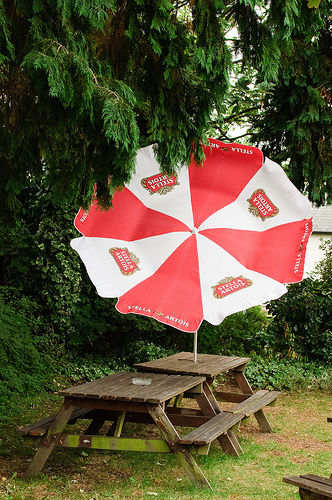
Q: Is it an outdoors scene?
A: Yes, it is outdoors.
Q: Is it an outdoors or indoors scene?
A: It is outdoors.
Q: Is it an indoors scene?
A: No, it is outdoors.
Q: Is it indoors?
A: No, it is outdoors.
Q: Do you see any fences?
A: No, there are no fences.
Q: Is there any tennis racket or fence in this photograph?
A: No, there are no fences or rackets.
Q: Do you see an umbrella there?
A: Yes, there is an umbrella.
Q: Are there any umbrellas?
A: Yes, there is an umbrella.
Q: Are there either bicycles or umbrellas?
A: Yes, there is an umbrella.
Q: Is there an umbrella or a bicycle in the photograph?
A: Yes, there is an umbrella.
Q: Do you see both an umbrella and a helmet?
A: No, there is an umbrella but no helmets.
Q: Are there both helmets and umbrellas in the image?
A: No, there is an umbrella but no helmets.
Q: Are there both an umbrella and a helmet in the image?
A: No, there is an umbrella but no helmets.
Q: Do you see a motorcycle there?
A: No, there are no motorcycles.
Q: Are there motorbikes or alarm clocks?
A: No, there are no motorbikes or alarm clocks.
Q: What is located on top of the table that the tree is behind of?
A: The umbrella is on top of the table.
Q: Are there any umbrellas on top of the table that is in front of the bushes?
A: Yes, there is an umbrella on top of the table.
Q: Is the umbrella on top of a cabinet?
A: No, the umbrella is on top of a table.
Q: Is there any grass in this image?
A: Yes, there is grass.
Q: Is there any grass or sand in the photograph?
A: Yes, there is grass.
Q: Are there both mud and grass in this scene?
A: No, there is grass but no mud.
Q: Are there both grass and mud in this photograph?
A: No, there is grass but no mud.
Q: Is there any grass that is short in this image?
A: Yes, there is short grass.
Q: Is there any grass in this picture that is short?
A: Yes, there is grass that is short.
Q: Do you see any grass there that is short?
A: Yes, there is grass that is short.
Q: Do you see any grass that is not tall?
A: Yes, there is short grass.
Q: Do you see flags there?
A: No, there are no flags.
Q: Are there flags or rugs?
A: No, there are no flags or rugs.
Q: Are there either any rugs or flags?
A: No, there are no flags or rugs.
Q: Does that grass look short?
A: Yes, the grass is short.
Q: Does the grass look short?
A: Yes, the grass is short.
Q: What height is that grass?
A: The grass is short.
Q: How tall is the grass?
A: The grass is short.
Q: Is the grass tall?
A: No, the grass is short.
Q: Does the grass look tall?
A: No, the grass is short.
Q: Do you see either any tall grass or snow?
A: No, there is grass but it is short.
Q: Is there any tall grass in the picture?
A: No, there is grass but it is short.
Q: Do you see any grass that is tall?
A: No, there is grass but it is short.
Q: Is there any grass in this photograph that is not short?
A: No, there is grass but it is short.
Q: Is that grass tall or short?
A: The grass is short.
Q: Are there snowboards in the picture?
A: No, there are no snowboards.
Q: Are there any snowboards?
A: No, there are no snowboards.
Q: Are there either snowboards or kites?
A: No, there are no snowboards or kites.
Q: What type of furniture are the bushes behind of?
A: The bushes are behind the table.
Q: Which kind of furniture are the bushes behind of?
A: The bushes are behind the table.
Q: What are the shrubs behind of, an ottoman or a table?
A: The shrubs are behind a table.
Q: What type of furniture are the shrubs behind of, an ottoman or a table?
A: The shrubs are behind a table.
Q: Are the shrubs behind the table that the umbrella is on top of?
A: Yes, the shrubs are behind the table.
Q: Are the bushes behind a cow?
A: No, the bushes are behind the table.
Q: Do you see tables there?
A: Yes, there is a table.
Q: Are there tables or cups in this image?
A: Yes, there is a table.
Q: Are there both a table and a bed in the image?
A: No, there is a table but no beds.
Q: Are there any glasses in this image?
A: No, there are no glasses.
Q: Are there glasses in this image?
A: No, there are no glasses.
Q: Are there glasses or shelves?
A: No, there are no glasses or shelves.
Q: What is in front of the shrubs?
A: The table is in front of the shrubs.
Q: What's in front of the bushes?
A: The table is in front of the shrubs.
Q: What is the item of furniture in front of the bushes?
A: The piece of furniture is a table.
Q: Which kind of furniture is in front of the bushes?
A: The piece of furniture is a table.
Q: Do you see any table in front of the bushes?
A: Yes, there is a table in front of the bushes.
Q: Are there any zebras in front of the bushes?
A: No, there is a table in front of the bushes.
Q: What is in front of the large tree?
A: The table is in front of the tree.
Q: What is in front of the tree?
A: The table is in front of the tree.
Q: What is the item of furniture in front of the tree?
A: The piece of furniture is a table.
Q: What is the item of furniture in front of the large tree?
A: The piece of furniture is a table.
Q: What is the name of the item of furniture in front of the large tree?
A: The piece of furniture is a table.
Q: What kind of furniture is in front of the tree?
A: The piece of furniture is a table.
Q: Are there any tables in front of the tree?
A: Yes, there is a table in front of the tree.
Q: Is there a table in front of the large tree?
A: Yes, there is a table in front of the tree.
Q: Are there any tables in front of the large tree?
A: Yes, there is a table in front of the tree.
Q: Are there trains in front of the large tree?
A: No, there is a table in front of the tree.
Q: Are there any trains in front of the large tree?
A: No, there is a table in front of the tree.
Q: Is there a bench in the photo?
A: Yes, there is a bench.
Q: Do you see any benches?
A: Yes, there is a bench.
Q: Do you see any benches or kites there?
A: Yes, there is a bench.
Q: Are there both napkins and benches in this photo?
A: No, there is a bench but no napkins.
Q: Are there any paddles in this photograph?
A: No, there are no paddles.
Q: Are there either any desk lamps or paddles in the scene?
A: No, there are no paddles or desk lamps.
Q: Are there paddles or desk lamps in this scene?
A: No, there are no paddles or desk lamps.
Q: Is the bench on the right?
A: Yes, the bench is on the right of the image.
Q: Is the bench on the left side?
A: No, the bench is on the right of the image.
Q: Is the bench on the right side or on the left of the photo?
A: The bench is on the right of the image.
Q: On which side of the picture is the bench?
A: The bench is on the right of the image.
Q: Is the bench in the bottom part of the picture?
A: Yes, the bench is in the bottom of the image.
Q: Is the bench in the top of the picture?
A: No, the bench is in the bottom of the image.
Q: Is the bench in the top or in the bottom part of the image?
A: The bench is in the bottom of the image.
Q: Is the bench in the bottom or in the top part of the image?
A: The bench is in the bottom of the image.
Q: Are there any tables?
A: Yes, there is a table.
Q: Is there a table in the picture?
A: Yes, there is a table.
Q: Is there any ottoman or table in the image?
A: Yes, there is a table.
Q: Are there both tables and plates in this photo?
A: No, there is a table but no plates.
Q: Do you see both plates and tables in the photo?
A: No, there is a table but no plates.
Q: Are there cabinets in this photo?
A: No, there are no cabinets.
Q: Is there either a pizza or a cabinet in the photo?
A: No, there are no cabinets or pizzas.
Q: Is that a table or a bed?
A: That is a table.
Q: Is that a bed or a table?
A: That is a table.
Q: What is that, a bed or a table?
A: That is a table.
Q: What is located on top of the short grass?
A: The table is on top of the grass.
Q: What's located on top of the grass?
A: The table is on top of the grass.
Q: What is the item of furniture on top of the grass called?
A: The piece of furniture is a table.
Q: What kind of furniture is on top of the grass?
A: The piece of furniture is a table.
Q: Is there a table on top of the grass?
A: Yes, there is a table on top of the grass.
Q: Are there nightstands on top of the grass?
A: No, there is a table on top of the grass.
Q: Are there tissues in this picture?
A: No, there are no tissues.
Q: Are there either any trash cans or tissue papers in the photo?
A: No, there are no tissue papers or trash cans.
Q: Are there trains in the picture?
A: No, there are no trains.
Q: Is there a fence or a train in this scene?
A: No, there are no trains or fences.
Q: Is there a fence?
A: No, there are no fences.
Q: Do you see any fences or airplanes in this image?
A: No, there are no fences or airplanes.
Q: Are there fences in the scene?
A: No, there are no fences.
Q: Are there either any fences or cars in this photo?
A: No, there are no fences or cars.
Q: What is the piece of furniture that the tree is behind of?
A: The piece of furniture is a table.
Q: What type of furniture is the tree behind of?
A: The tree is behind the table.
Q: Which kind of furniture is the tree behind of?
A: The tree is behind the table.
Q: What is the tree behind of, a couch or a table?
A: The tree is behind a table.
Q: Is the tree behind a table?
A: Yes, the tree is behind a table.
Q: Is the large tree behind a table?
A: Yes, the tree is behind a table.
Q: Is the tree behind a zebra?
A: No, the tree is behind a table.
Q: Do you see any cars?
A: No, there are no cars.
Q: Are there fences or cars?
A: No, there are no cars or fences.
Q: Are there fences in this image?
A: No, there are no fences.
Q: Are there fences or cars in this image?
A: No, there are no fences or cars.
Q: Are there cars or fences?
A: No, there are no fences or cars.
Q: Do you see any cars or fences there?
A: No, there are no fences or cars.